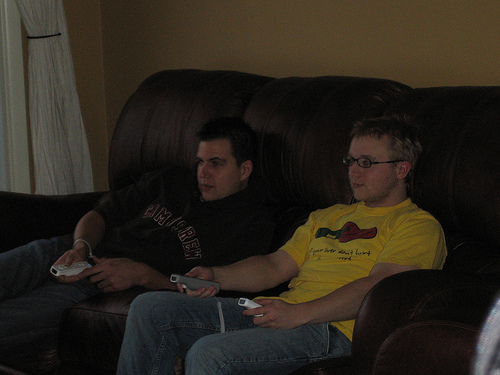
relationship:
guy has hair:
[117, 113, 449, 375] [349, 117, 421, 161]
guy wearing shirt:
[117, 113, 449, 375] [277, 200, 449, 347]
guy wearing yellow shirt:
[117, 113, 449, 375] [251, 199, 448, 341]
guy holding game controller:
[117, 113, 449, 375] [165, 268, 217, 294]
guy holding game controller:
[117, 113, 449, 375] [233, 295, 269, 324]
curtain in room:
[4, 0, 96, 193] [4, 2, 497, 372]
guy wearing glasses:
[117, 113, 449, 375] [341, 153, 405, 167]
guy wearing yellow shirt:
[117, 113, 449, 375] [245, 190, 445, 340]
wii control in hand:
[44, 261, 94, 278] [47, 242, 94, 279]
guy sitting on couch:
[117, 113, 449, 375] [0, 67, 499, 373]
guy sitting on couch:
[0, 120, 266, 344] [0, 67, 499, 373]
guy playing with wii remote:
[303, 101, 425, 327] [157, 264, 219, 299]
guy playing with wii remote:
[303, 101, 425, 327] [225, 285, 281, 321]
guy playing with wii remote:
[136, 102, 255, 264] [39, 247, 96, 281]